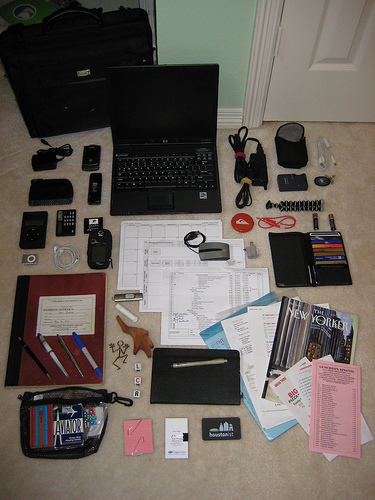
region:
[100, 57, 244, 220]
open black laptop on floor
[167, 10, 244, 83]
green wall behind laptop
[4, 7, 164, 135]
black bag with handle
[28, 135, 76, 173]
power cord in front of case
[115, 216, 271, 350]
three pages arranged on floor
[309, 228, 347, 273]
credit cards in slots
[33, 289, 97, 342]
label on red notebook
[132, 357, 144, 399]
letters on three blocks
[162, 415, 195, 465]
clip on white card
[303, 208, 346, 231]
two batteries on floor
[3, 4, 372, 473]
various items spread out on the carpet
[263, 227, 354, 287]
wallet with credit cards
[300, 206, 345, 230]
two batteries on the carpet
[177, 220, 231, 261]
external mouse with its cord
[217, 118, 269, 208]
black cords on the carpet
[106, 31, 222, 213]
black laptop near wall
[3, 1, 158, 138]
black laptop case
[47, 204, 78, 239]
small calculator on the carpet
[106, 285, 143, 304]
a flash drive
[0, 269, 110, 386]
four pens on a red notepad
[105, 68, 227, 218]
this is a laptop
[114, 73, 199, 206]
the laptop is black in color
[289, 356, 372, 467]
these are some pamphlets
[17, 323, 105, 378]
these are some pens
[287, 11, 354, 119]
this is a door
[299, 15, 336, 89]
the door is white in color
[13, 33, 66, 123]
this is a bag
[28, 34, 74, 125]
the bag is black in color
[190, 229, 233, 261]
this is a mouse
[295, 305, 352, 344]
this is a magazine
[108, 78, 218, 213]
the laptop is on the floor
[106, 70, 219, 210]
the laptop is off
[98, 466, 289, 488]
the carpet is carpeted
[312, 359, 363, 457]
the paper is pink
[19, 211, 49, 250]
there is an ipod on the floor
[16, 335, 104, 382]
there are four pens on the book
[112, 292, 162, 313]
there is a usb on the carpet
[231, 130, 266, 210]
the cable is on the floor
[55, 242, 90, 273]
thre are earphones on the floor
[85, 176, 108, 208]
there is a remote on the carpet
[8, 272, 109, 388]
red booklet with black binder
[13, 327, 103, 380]
four pens on booklet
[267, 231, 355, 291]
open wallet with credit cards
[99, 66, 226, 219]
open laptop on floor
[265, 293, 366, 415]
magazine under three pamplets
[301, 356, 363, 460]
pink pamphlet with black words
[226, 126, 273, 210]
black power cord on floor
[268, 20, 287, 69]
hinge on white door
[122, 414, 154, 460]
pink card with two clips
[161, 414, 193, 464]
white card with one clip